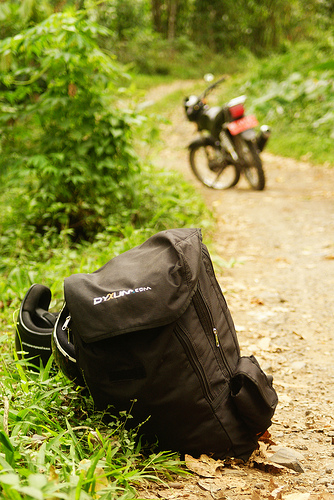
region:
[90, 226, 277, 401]
A backpack is on the ground.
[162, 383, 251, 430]
The backpack is black.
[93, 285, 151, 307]
A brand name is on the backpack.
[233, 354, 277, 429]
The backpack has a pocket.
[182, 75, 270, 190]
A motorbike is on the trail.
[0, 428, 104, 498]
The ground is covered with grass.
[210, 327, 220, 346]
The backpack has a zipper.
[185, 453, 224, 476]
Leaves are on the ground.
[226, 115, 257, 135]
A red license plate is on the motorbike.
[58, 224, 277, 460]
a large black bag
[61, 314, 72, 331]
a zipper on a bag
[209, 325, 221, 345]
a zipper on a bag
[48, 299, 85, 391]
A black helmet on the ground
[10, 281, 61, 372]
A black helmet on the ground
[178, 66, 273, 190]
a small motorcycle on a path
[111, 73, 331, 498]
a thin dirt path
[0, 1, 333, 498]
A large wooded area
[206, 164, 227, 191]
a kickstand on a motorcycle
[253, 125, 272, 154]
an exhaust pipe on a motorcycle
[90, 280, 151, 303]
logo on the bag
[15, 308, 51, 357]
a helmet on the grass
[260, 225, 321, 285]
the road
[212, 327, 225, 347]
a zipper on the bag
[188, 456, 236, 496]
brown leaves on the ground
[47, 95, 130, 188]
the leaves on the tree is green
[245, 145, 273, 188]
the tire on the back of the motorcycle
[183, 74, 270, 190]
motorbike parked on road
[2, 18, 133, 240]
green leaves on bush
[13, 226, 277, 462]
bag and two helmets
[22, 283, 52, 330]
cushion inside of helmet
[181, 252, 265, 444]
zipper on side of bag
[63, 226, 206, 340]
closed cover of bag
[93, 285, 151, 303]
white logo on black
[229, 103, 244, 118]
red square brake light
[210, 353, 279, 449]
pouch on side of bag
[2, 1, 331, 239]
green leaves on vegetation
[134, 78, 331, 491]
dirt road in the woods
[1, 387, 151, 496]
blades of green weeds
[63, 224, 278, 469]
nylon bag on ground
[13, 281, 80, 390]
two black helmets on ground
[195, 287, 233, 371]
zipper on side of bag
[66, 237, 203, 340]
bag cover with logo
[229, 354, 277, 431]
strap over bag pouch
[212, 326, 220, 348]
metal tag of zipper